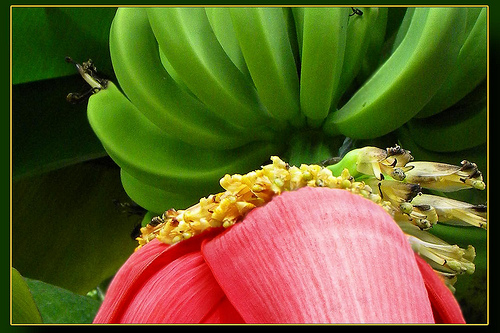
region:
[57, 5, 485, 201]
bananas on the plant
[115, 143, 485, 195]
you can see where other bunches were cut off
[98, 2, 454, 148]
the bananas are green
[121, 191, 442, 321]
the plant appears to be pink/red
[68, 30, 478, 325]
it appears there will be many bunches of bananas in the future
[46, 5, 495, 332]
a very unique photo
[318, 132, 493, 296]
Banana flowers?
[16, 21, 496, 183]
a lot of green is in the photo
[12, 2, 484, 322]
few people have seen the bananas on the plant as in this photo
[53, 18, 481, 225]
the bunch of bananas is huge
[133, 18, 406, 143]
green stem flower petals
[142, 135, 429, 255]
yellow small flower petals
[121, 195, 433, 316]
a big red flower petal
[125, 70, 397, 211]
curved green flower petals.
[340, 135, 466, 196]
green black and yellow petals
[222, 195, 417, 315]
red petals with small lines in it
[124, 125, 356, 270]
yellow sun flower petals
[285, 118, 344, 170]
a green stem on a flower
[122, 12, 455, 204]
multiple green flower petals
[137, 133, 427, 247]
multiple yellow flower petals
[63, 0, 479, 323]
red plant with bananas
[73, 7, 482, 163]
green bananas on plant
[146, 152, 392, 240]
yellow seeds on plant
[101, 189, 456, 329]
red leaves on plant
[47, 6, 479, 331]
plant with red leaves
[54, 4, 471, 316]
plant with green bananas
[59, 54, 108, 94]
black stem on banana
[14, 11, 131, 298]
large green leaf of plant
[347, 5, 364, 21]
black bug on banana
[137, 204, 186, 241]
brown seeds on plant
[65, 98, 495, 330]
a red flower outside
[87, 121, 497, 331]
a bloomed flower outside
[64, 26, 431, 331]
a flower under bananas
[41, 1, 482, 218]
green bananas outside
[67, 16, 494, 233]
a bunch of green bananas outside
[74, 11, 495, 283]
green bananas that are outside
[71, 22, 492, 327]
green bananas above the flower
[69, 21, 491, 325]
flower under the green bananas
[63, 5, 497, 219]
bunch of green plantains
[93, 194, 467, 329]
red leaves beneath green plantains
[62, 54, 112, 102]
end of green plantains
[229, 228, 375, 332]
ridged texture of red leaves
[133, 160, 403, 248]
yellow top of red leaves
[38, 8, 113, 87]
shadow of green plantain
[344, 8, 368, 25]
black insect on green plantain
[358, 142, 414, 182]
end of yellow flower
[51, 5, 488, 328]
bunch of green plantains on top of red plant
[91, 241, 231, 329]
curved downturned red leaf